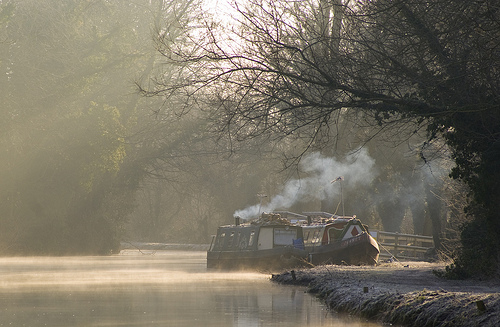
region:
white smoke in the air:
[268, 161, 388, 211]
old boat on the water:
[188, 195, 395, 265]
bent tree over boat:
[146, 36, 463, 129]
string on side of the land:
[361, 228, 422, 272]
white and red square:
[340, 219, 375, 241]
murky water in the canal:
[36, 253, 212, 308]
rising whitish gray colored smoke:
[234, 144, 453, 219]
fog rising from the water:
[0, 242, 375, 325]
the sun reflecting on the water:
[0, 246, 271, 290]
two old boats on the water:
[203, 208, 378, 269]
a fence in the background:
[374, 226, 433, 259]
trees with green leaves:
[1, 53, 150, 255]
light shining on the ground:
[339, 258, 450, 270]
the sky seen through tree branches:
[156, 0, 366, 131]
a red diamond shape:
[348, 224, 360, 236]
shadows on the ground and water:
[0, 268, 499, 325]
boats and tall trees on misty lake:
[16, 16, 488, 312]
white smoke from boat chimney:
[200, 145, 452, 270]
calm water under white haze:
[5, 241, 368, 322]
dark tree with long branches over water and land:
[138, 5, 494, 320]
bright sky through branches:
[149, 2, 369, 118]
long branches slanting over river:
[7, 4, 224, 261]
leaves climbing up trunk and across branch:
[360, 75, 488, 282]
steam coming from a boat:
[228, 146, 373, 223]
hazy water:
[1, 235, 398, 325]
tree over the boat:
[126, 1, 498, 283]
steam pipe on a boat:
[232, 212, 243, 226]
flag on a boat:
[330, 171, 350, 219]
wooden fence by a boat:
[372, 223, 442, 267]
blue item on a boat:
[288, 233, 306, 251]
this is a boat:
[165, 163, 402, 307]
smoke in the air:
[209, 122, 396, 217]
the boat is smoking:
[166, 176, 405, 293]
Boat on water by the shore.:
[196, 196, 382, 276]